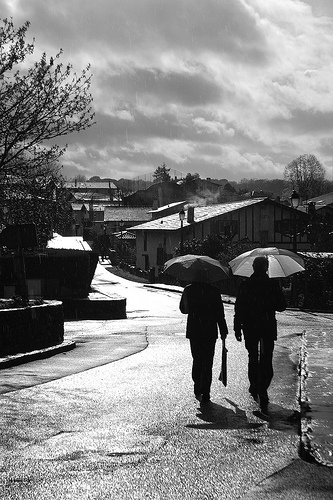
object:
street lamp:
[290, 187, 299, 304]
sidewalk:
[149, 281, 299, 310]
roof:
[122, 190, 269, 231]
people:
[177, 256, 232, 416]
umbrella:
[228, 246, 307, 291]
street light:
[174, 205, 189, 224]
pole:
[178, 217, 186, 257]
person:
[231, 250, 290, 423]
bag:
[216, 336, 230, 390]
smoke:
[186, 188, 219, 207]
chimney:
[187, 205, 194, 222]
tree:
[283, 148, 327, 207]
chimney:
[151, 196, 158, 208]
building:
[126, 195, 309, 280]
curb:
[1, 312, 154, 397]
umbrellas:
[157, 252, 238, 292]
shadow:
[184, 395, 265, 436]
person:
[177, 257, 230, 418]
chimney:
[73, 177, 79, 186]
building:
[50, 175, 117, 197]